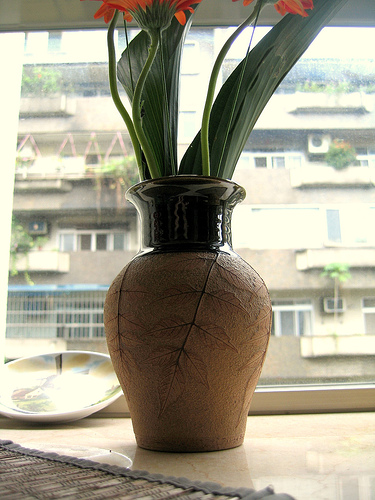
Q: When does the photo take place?
A: During daytime.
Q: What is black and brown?
A: Vase.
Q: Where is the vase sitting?
A: On window sill.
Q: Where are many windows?
A: On a building.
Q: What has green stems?
A: The flowers.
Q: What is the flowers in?
A: The vase.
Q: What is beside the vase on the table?
A: A mat.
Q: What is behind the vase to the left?
A: A plate.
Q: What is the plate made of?
A: Ceramic.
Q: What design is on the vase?
A: A leaf design.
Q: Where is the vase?
A: In the window seal.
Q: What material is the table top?
A: Marble.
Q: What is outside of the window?
A: A building.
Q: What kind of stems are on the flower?
A: Long stems.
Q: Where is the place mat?
A: On the table top.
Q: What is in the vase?
A: Flowers.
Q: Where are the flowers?
A: In the vase.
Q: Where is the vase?
A: By the window.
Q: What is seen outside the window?
A: A building.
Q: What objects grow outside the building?
A: Plants.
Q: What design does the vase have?
A: Leaves.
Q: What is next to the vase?
A: A plate.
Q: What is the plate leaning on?
A: The window.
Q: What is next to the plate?
A: A vase.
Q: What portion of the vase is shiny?
A: The top.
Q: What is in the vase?
A: Flowers.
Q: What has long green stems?
A: Flowers.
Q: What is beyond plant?
A: Buildings.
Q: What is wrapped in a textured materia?
A: Vase.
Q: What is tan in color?
A: Vase.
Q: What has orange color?
A: Flowers.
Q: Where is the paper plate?
A: Near window.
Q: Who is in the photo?
A: Nobody.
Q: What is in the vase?
A: A plant.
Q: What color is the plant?
A: Green.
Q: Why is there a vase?
A: To hold the plant.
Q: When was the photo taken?
A: Daytime.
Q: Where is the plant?
A: In the vase.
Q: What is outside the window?
A: A building.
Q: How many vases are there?
A: One.